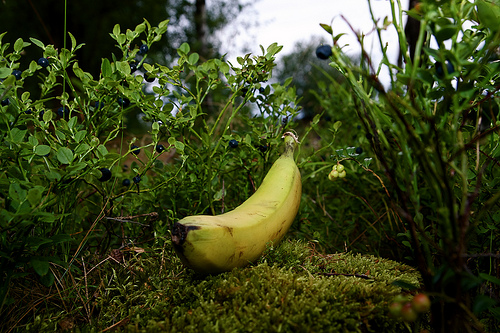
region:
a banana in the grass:
[151, 74, 383, 285]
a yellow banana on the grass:
[130, 104, 347, 323]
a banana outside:
[164, 49, 346, 298]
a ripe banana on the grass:
[132, 52, 368, 282]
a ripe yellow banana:
[121, 46, 382, 291]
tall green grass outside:
[282, 16, 484, 268]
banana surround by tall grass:
[47, 34, 444, 320]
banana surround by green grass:
[86, 17, 376, 320]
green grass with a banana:
[21, 32, 497, 319]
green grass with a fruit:
[27, 42, 433, 331]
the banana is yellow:
[175, 107, 349, 324]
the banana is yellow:
[186, 140, 280, 287]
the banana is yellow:
[162, 80, 288, 270]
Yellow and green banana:
[164, 133, 312, 273]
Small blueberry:
[313, 33, 335, 62]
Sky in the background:
[217, 0, 404, 72]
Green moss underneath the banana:
[97, 252, 417, 327]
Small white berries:
[322, 154, 349, 186]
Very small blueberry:
[225, 135, 237, 150]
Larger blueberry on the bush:
[93, 160, 113, 185]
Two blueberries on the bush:
[10, 48, 50, 89]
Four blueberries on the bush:
[110, 30, 173, 110]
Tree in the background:
[176, 3, 234, 57]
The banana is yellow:
[172, 131, 302, 267]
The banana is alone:
[174, 131, 304, 271]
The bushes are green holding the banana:
[51, 238, 430, 328]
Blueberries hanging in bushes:
[1, 1, 494, 190]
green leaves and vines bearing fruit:
[1, 2, 499, 332]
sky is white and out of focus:
[128, 2, 496, 119]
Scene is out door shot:
[1, 1, 498, 331]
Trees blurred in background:
[1, 2, 370, 118]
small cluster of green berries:
[328, 161, 344, 184]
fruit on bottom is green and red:
[384, 286, 431, 325]